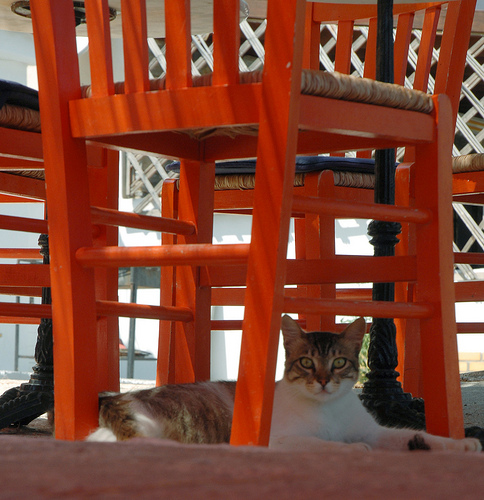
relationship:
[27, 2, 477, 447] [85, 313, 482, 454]
chair above cat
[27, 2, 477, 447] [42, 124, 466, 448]
chair has legs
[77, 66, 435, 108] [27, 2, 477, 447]
cushion on chair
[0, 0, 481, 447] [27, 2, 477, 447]
table behind chair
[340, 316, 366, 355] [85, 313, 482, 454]
ear on cat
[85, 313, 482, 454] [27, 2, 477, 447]
cat under chair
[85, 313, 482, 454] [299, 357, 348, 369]
cat has eyes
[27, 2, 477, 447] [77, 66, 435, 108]
chair has a cushion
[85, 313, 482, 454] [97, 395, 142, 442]
cat has a tail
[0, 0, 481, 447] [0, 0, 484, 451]
table has a post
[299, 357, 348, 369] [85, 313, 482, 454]
eyes are on cat